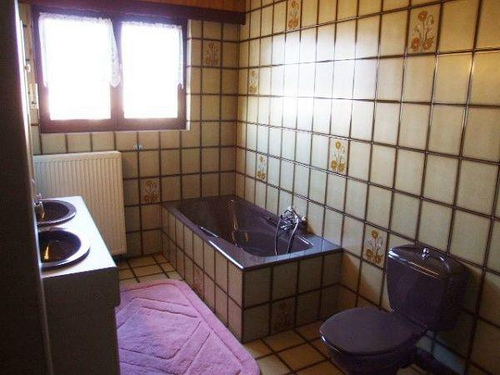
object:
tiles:
[37, 1, 500, 375]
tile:
[160, 196, 344, 346]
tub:
[159, 181, 345, 368]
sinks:
[35, 194, 120, 375]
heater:
[29, 150, 128, 257]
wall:
[14, 11, 247, 287]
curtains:
[37, 1, 185, 89]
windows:
[35, 11, 189, 132]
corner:
[188, 6, 271, 197]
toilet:
[311, 238, 488, 374]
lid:
[318, 306, 420, 356]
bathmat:
[78, 280, 259, 375]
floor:
[51, 258, 400, 375]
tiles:
[328, 137, 348, 176]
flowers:
[330, 160, 346, 172]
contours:
[178, 196, 313, 256]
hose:
[274, 216, 300, 256]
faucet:
[279, 207, 308, 232]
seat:
[316, 297, 422, 375]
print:
[327, 136, 349, 177]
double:
[31, 198, 91, 270]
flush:
[421, 247, 431, 258]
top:
[382, 237, 474, 332]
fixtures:
[274, 204, 309, 257]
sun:
[42, 81, 186, 121]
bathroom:
[0, 0, 497, 375]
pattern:
[405, 3, 438, 57]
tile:
[402, 4, 440, 58]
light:
[262, 36, 374, 136]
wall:
[242, 5, 496, 349]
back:
[385, 245, 471, 330]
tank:
[385, 241, 467, 330]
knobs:
[280, 205, 307, 231]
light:
[39, 14, 184, 121]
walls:
[21, 16, 490, 322]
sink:
[38, 226, 91, 270]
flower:
[410, 37, 424, 52]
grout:
[328, 133, 498, 166]